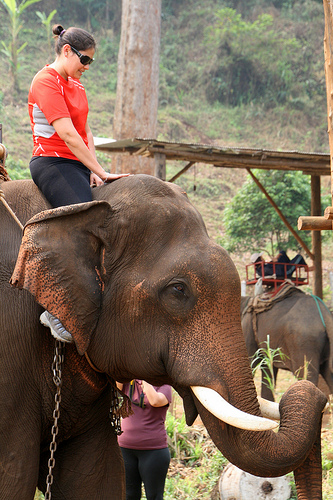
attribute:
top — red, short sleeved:
[23, 68, 96, 164]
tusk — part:
[249, 386, 292, 418]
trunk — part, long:
[246, 382, 331, 491]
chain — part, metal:
[35, 344, 75, 491]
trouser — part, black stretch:
[30, 156, 99, 212]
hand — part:
[86, 165, 111, 190]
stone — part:
[209, 468, 293, 500]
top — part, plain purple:
[115, 384, 173, 456]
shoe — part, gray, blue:
[32, 307, 79, 348]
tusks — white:
[185, 369, 325, 445]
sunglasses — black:
[63, 39, 96, 67]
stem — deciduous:
[107, 6, 173, 166]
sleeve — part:
[149, 382, 179, 414]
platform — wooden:
[96, 133, 332, 180]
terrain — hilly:
[92, 6, 329, 188]